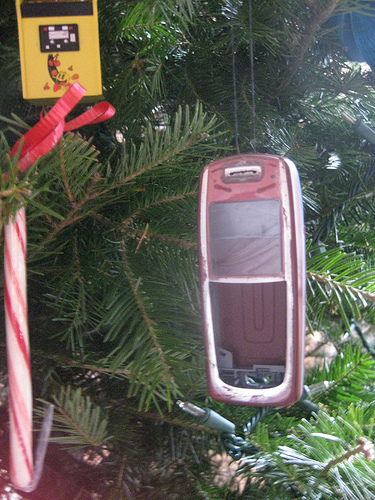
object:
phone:
[197, 153, 305, 406]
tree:
[0, 98, 237, 418]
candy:
[4, 206, 33, 491]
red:
[3, 270, 31, 375]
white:
[4, 217, 27, 307]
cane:
[9, 212, 24, 340]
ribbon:
[0, 81, 115, 187]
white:
[175, 400, 206, 418]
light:
[176, 398, 237, 433]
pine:
[84, 173, 100, 198]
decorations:
[15, 0, 105, 105]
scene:
[0, 0, 374, 498]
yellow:
[14, 0, 102, 100]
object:
[14, 0, 105, 105]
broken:
[218, 281, 286, 367]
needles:
[152, 128, 160, 164]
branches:
[89, 176, 125, 199]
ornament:
[320, 0, 375, 73]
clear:
[208, 198, 283, 276]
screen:
[198, 161, 293, 281]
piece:
[206, 157, 282, 207]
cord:
[220, 406, 275, 460]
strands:
[217, 1, 272, 159]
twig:
[119, 130, 210, 186]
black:
[20, 0, 93, 19]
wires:
[244, 437, 302, 490]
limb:
[36, 132, 210, 240]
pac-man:
[44, 53, 79, 92]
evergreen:
[0, 0, 375, 500]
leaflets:
[129, 143, 136, 174]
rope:
[228, 0, 258, 155]